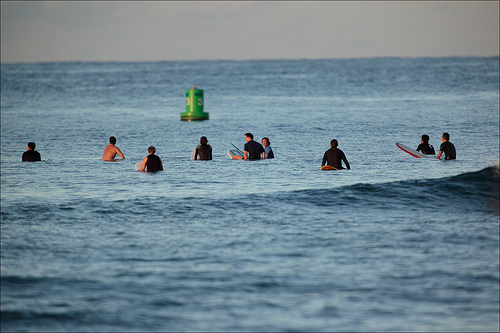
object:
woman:
[259, 137, 275, 158]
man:
[193, 135, 215, 160]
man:
[417, 133, 434, 157]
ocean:
[3, 55, 497, 332]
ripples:
[187, 205, 260, 256]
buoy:
[177, 83, 213, 124]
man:
[23, 140, 42, 163]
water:
[1, 57, 500, 333]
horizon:
[0, 52, 499, 64]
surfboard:
[393, 140, 423, 158]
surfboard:
[319, 164, 336, 171]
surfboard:
[227, 147, 244, 161]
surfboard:
[134, 161, 145, 171]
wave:
[162, 174, 490, 214]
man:
[99, 134, 125, 161]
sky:
[0, 4, 499, 60]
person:
[234, 128, 264, 161]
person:
[437, 132, 459, 160]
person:
[137, 145, 166, 173]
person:
[320, 136, 352, 168]